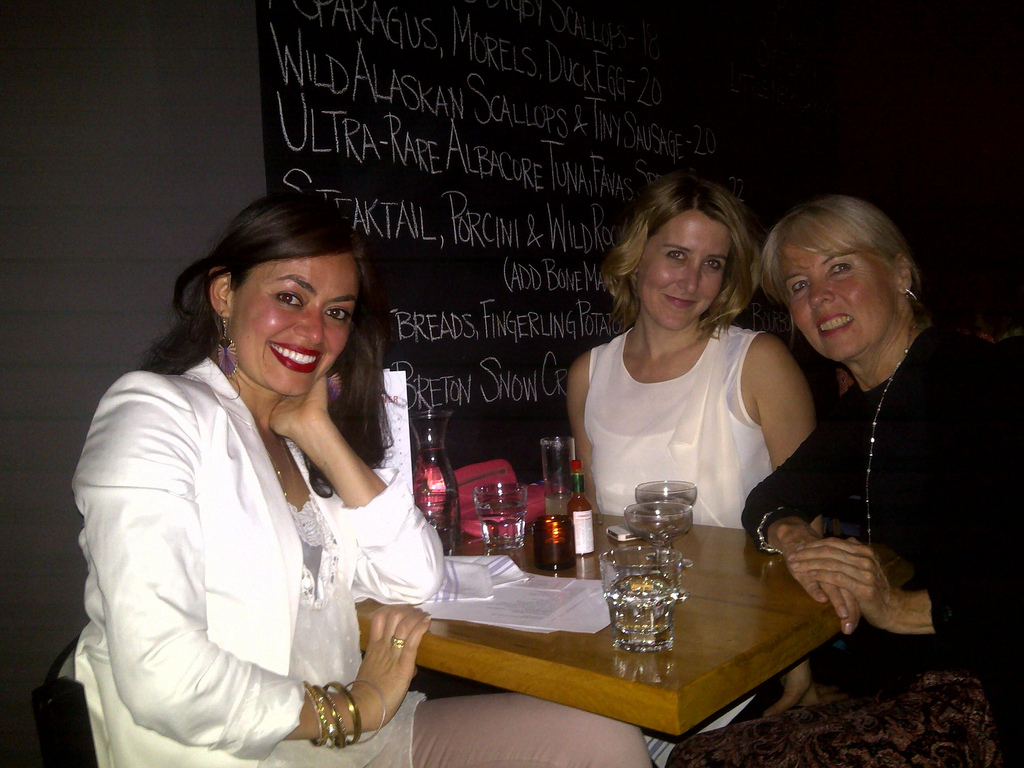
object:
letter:
[462, 314, 475, 339]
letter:
[451, 312, 464, 340]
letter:
[425, 314, 441, 341]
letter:
[413, 311, 429, 343]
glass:
[599, 546, 684, 654]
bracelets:
[343, 681, 386, 746]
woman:
[666, 196, 1024, 768]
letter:
[419, 207, 436, 240]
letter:
[269, 22, 304, 85]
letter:
[276, 91, 308, 152]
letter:
[480, 357, 502, 403]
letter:
[395, 311, 415, 341]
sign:
[255, 0, 721, 492]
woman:
[76, 194, 646, 768]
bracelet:
[302, 681, 349, 752]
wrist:
[284, 683, 397, 741]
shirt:
[581, 323, 776, 531]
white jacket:
[76, 356, 449, 768]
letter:
[480, 299, 496, 338]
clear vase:
[413, 410, 462, 557]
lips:
[268, 339, 323, 374]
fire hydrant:
[451, 458, 566, 540]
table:
[358, 518, 854, 739]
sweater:
[739, 326, 1024, 766]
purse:
[432, 457, 567, 540]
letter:
[310, 108, 330, 153]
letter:
[353, 37, 378, 103]